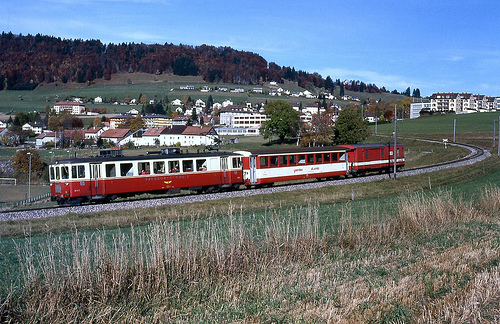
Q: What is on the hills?
A: Trees.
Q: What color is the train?
A: Red and white.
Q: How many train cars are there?
A: 3.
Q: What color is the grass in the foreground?
A: Brown.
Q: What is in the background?
A: Trees.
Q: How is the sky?
A: Clear and blue.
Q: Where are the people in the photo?
A: On the train.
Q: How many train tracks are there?
A: 1.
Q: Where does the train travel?
A: Around the town.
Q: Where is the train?
A: On the track.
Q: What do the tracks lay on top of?
A: The rocks.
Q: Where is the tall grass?
A: In the field.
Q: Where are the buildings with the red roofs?
A: On the left.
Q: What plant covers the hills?
A: Trees.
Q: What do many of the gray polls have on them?
A: Lights.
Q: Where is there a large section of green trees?
A: On the hill.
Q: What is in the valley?
A: A small village.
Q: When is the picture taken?
A: Daytime.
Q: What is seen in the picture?
A: Train.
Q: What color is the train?
A: Red and white.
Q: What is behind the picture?
A: Trees.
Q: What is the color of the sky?
A: Blue.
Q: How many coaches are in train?
A: 3.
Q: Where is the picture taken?
A: In a small town.